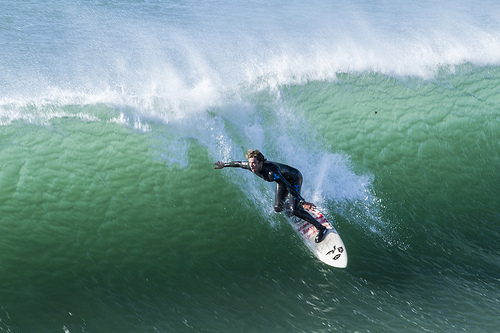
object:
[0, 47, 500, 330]
wave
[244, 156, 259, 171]
brick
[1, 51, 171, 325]
water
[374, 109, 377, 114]
debris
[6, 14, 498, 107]
sea spray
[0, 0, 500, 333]
ocean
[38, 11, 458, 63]
spray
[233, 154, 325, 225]
wet suit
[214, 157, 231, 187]
right hand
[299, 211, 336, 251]
surfing boots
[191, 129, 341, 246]
surfter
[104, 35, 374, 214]
spraying water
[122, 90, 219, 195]
splash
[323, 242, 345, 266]
paint job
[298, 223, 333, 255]
foot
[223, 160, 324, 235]
wetsuit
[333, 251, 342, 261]
black sticker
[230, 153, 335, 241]
wetsuit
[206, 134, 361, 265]
surfer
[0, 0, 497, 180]
wave crest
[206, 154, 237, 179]
surfers hand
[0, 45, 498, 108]
white water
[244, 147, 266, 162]
hair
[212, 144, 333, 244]
man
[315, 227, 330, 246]
shoes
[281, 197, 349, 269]
surfboard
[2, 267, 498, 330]
water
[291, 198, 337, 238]
stripes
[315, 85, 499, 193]
body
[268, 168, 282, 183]
logo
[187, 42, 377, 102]
splash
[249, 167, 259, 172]
mouth